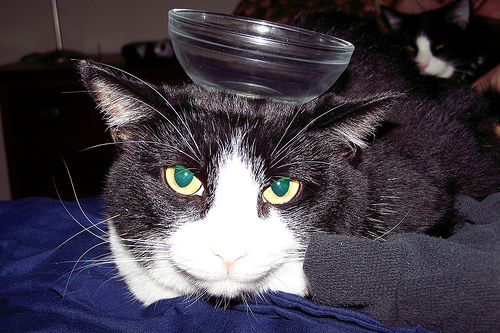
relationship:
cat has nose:
[16, 60, 413, 313] [207, 235, 260, 289]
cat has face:
[16, 60, 413, 313] [124, 130, 325, 255]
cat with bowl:
[16, 60, 413, 313] [158, 16, 345, 103]